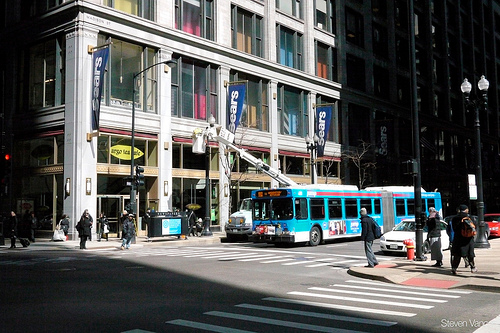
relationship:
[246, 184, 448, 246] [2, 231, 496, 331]
bus on road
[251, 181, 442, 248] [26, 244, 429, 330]
blue bus on street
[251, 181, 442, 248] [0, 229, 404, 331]
blue bus on street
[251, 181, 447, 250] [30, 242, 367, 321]
blue bus on road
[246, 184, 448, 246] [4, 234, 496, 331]
bus on street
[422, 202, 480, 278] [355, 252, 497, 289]
people on sidewalk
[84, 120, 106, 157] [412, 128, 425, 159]
signal on pole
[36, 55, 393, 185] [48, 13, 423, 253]
signs on building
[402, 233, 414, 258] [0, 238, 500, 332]
fire hydrant on road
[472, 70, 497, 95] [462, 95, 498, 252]
light on pole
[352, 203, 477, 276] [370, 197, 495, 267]
people on sidewalk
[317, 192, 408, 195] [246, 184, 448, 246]
red stripe on bus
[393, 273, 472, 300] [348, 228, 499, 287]
block painted on sidewalk